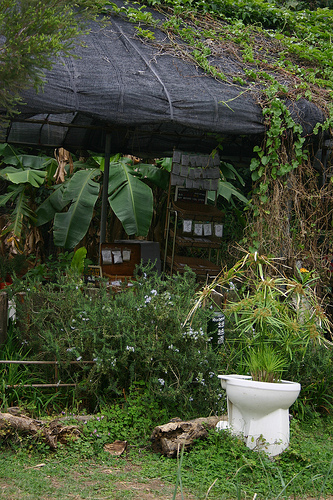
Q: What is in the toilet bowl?
A: A plant.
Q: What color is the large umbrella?
A: Black.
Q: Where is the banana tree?
A: Behind the black roofing.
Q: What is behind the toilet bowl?
A: A log.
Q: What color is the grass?
A: Green.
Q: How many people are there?
A: None.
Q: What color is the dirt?
A: Brown.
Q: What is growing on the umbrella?
A: Plants.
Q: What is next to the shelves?
A: Plants.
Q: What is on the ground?
A: Grass.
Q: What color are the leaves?
A: Green.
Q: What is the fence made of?
A: Metal.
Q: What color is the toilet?
A: White.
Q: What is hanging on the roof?
A: Vines.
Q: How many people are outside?
A: None.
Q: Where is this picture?
A: The jungle.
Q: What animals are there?
A: None.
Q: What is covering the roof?
A: Ivy.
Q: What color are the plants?
A: Green.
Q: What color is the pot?
A: White.